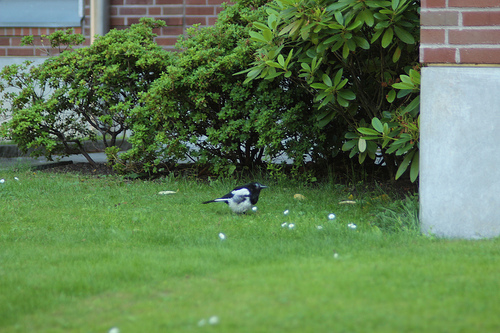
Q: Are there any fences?
A: No, there are no fences.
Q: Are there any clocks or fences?
A: No, there are no fences or clocks.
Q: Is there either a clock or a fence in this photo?
A: No, there are no fences or clocks.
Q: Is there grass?
A: Yes, there is grass.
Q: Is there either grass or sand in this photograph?
A: Yes, there is grass.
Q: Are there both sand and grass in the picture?
A: No, there is grass but no sand.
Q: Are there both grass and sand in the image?
A: No, there is grass but no sand.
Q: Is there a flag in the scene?
A: No, there are no flags.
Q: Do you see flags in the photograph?
A: No, there are no flags.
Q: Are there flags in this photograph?
A: No, there are no flags.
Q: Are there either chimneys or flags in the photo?
A: No, there are no flags or chimneys.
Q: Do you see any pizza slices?
A: No, there are no pizza slices.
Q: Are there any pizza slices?
A: No, there are no pizza slices.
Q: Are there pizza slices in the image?
A: No, there are no pizza slices.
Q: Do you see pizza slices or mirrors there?
A: No, there are no pizza slices or mirrors.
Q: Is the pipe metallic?
A: Yes, the pipe is metallic.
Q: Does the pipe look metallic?
A: Yes, the pipe is metallic.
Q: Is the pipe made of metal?
A: Yes, the pipe is made of metal.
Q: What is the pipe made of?
A: The pipe is made of metal.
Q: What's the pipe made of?
A: The pipe is made of metal.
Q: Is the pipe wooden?
A: No, the pipe is metallic.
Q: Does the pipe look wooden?
A: No, the pipe is metallic.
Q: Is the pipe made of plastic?
A: No, the pipe is made of metal.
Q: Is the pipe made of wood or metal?
A: The pipe is made of metal.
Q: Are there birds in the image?
A: Yes, there is a bird.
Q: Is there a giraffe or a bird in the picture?
A: Yes, there is a bird.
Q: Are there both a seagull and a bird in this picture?
A: No, there is a bird but no seagulls.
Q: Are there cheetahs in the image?
A: No, there are no cheetahs.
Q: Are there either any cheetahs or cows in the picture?
A: No, there are no cheetahs or cows.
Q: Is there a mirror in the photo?
A: No, there are no mirrors.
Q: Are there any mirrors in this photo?
A: No, there are no mirrors.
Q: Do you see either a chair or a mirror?
A: No, there are no mirrors or chairs.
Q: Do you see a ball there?
A: No, there are no balls.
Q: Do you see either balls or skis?
A: No, there are no balls or skis.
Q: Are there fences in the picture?
A: No, there are no fences.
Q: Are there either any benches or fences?
A: No, there are no fences or benches.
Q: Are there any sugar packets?
A: No, there are no sugar packets.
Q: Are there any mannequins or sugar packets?
A: No, there are no sugar packets or mannequins.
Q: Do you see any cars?
A: No, there are no cars.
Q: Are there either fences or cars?
A: No, there are no cars or fences.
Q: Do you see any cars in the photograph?
A: No, there are no cars.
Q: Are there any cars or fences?
A: No, there are no cars or fences.